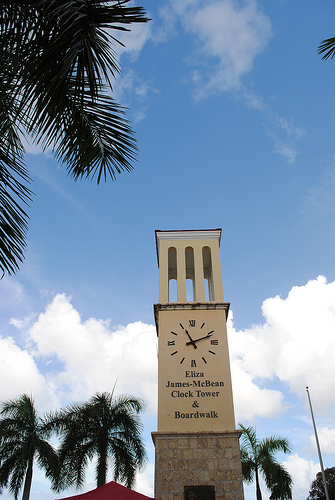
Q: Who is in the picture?
A: No one.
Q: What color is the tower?
A: Tan.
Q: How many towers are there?
A: 1.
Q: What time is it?
A: 11:11.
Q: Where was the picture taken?
A: Outside in a plaza.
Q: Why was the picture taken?
A: To capture the tower.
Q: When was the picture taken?
A: In the daytime.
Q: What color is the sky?
A: Blue and white.